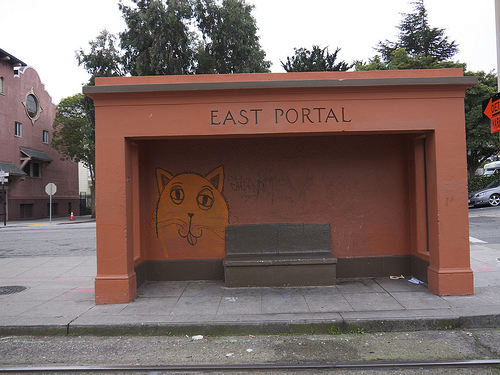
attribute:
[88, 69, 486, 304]
bus stop — brown, red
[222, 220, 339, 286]
bench — wood, brown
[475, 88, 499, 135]
sign — orange, black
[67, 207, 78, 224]
cone — orange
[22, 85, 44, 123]
window — circle, small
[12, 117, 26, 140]
window — small